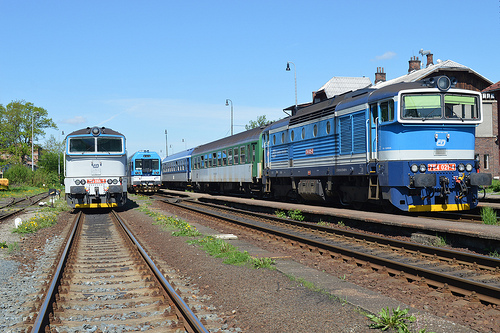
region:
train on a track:
[46, 116, 144, 226]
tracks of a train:
[48, 226, 179, 318]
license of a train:
[425, 155, 458, 177]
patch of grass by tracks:
[211, 233, 272, 272]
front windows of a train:
[396, 78, 482, 129]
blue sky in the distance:
[25, 35, 202, 90]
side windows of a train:
[191, 138, 256, 166]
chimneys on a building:
[402, 50, 434, 72]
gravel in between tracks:
[188, 255, 263, 327]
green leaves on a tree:
[3, 97, 54, 192]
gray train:
[54, 123, 134, 204]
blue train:
[260, 100, 476, 196]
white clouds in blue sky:
[15, 15, 51, 48]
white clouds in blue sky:
[57, 47, 114, 82]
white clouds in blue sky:
[62, 15, 126, 59]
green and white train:
[177, 128, 281, 179]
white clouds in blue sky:
[132, 43, 187, 105]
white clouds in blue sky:
[142, 13, 193, 50]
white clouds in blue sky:
[204, 10, 250, 64]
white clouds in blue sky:
[315, 18, 365, 60]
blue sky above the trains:
[111, 10, 227, 67]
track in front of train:
[41, 213, 158, 295]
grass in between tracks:
[196, 227, 276, 282]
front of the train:
[386, 73, 490, 193]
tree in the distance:
[1, 111, 46, 158]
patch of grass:
[241, 245, 286, 287]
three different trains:
[18, 90, 450, 249]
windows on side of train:
[175, 140, 257, 181]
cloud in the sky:
[125, 83, 171, 120]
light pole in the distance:
[211, 90, 244, 123]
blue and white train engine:
[271, 68, 459, 209]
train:
[58, 132, 129, 209]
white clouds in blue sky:
[35, 15, 83, 53]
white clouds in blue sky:
[67, 63, 134, 118]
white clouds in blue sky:
[88, 26, 173, 98]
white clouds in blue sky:
[155, 68, 199, 150]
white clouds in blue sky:
[231, 23, 275, 74]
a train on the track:
[43, 118, 170, 330]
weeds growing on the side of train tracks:
[242, 255, 413, 331]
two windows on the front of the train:
[64, 132, 123, 194]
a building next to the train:
[0, 138, 43, 175]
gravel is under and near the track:
[0, 227, 152, 331]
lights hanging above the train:
[208, 49, 300, 134]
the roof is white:
[306, 60, 465, 95]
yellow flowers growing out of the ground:
[141, 199, 201, 261]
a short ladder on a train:
[368, 174, 380, 199]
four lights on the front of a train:
[404, 163, 473, 173]